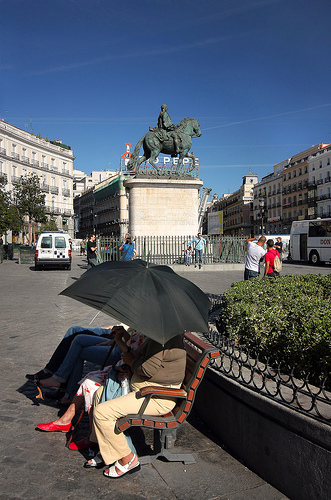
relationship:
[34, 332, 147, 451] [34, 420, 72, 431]
lady wearing red shoes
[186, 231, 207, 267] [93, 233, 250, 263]
man standing against fence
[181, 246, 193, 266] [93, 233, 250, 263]
child standing against fence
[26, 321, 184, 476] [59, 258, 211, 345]
people sitting under umbrella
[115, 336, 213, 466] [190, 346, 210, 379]
bench made of wood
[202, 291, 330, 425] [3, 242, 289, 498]
fence around sidewalk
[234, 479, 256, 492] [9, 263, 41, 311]
crack in sidewalk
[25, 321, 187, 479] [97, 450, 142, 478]
people wearing sandals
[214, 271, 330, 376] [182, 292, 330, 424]
bush in middle of fence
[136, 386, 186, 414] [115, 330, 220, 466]
arm on bench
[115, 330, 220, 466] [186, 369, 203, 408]
bench made of wood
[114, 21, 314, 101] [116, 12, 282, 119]
large area of sky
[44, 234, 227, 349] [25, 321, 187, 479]
umbrella held by people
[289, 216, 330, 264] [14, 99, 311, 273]
bus in background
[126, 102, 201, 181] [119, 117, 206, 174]
statue on a horse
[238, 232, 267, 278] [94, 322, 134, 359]
man taking photo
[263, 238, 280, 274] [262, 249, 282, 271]
man with a shirt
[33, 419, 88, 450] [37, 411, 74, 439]
red shoes on feet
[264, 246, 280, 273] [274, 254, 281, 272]
shirt with backpack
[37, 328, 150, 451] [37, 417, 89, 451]
lady wearing red shoes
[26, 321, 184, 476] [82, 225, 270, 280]
people sitting on a bench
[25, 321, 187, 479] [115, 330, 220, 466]
people sitting on a bench